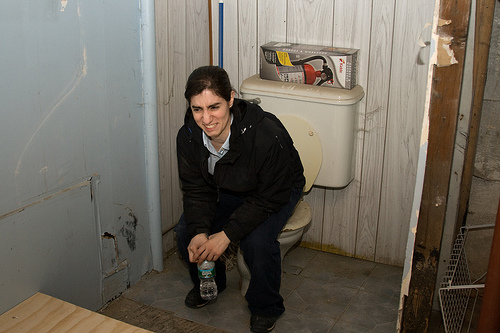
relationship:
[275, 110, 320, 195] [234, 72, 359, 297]
lid on toilet bowl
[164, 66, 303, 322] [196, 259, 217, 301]
woman holding bottle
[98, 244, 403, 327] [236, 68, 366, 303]
floor around toilet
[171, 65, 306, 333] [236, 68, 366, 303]
woman sitting on toilet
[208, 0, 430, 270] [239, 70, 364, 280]
panels behind toilet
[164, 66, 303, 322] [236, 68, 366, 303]
woman on toilet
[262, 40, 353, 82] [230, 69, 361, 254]
extinguisher on toilet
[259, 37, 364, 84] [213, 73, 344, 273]
box on toilet